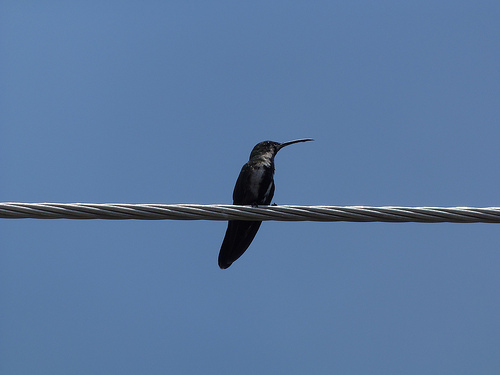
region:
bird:
[205, 122, 304, 269]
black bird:
[223, 125, 288, 255]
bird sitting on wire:
[225, 117, 285, 282]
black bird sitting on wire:
[230, 137, 283, 279]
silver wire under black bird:
[2, 196, 487, 226]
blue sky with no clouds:
[12, 7, 177, 180]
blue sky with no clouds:
[172, 15, 472, 105]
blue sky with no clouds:
[325, 120, 472, 197]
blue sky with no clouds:
[265, 225, 476, 350]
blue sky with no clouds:
[14, 232, 211, 346]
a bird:
[129, 82, 315, 322]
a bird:
[170, 87, 390, 369]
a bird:
[179, 136, 301, 349]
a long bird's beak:
[281, 129, 318, 155]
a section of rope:
[13, 173, 175, 240]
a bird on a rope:
[214, 129, 313, 296]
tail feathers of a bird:
[191, 218, 307, 275]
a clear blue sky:
[35, 17, 472, 134]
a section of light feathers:
[208, 158, 294, 197]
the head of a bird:
[242, 126, 324, 171]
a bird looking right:
[208, 96, 309, 306]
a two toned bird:
[198, 124, 317, 272]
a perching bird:
[207, 118, 367, 277]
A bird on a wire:
[171, 107, 356, 274]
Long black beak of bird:
[278, 132, 313, 152]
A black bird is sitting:
[218, 121, 318, 299]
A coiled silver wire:
[7, 193, 499, 231]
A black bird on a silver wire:
[206, 116, 325, 272]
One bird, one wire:
[203, 108, 342, 298]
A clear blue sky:
[5, 3, 490, 362]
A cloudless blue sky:
[8, 9, 488, 361]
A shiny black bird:
[203, 113, 330, 274]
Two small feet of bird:
[244, 199, 286, 210]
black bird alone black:
[215, 112, 307, 269]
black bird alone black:
[235, 160, 310, 290]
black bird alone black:
[205, 140, 275, 275]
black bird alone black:
[240, 145, 275, 275]